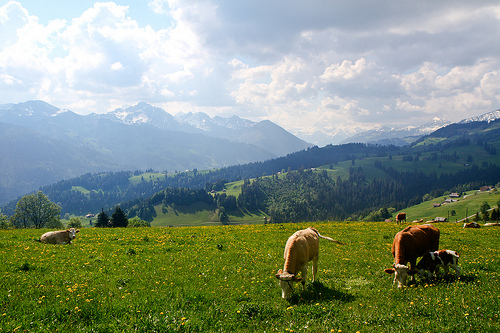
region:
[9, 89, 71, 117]
highest peak in distance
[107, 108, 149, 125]
white snow on mountain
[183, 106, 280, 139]
group of mountains far off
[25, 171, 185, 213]
green hill covered in trees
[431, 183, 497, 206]
group of buildings on hill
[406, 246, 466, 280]
small calf by red cow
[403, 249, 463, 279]
calf is red and white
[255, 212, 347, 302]
can is cream colored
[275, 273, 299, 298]
white face of eating cow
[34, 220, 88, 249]
cow laying in green meadow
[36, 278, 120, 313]
Yellow flowers in the class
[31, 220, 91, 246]
A cow looking guilty in the field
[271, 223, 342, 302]
A yellow cow eating grass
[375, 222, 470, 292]
A cow and her baby eating together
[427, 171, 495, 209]
Houses in a community on the mountain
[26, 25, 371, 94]
The sky is cloudy and blue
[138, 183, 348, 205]
Trees on a mountain with green leaves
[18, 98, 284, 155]
Very tall mountains clustered together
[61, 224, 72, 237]
The ear of a cow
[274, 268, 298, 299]
The head of a cow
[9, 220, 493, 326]
lush green grass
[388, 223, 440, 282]
the brown cow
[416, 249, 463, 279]
the small brown and white cow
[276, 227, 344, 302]
the light colored cow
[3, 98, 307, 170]
the mountains in the far distance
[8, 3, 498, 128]
the clouds in the sky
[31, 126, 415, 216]
the trees in the mountain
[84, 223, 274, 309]
the yellow flowers on the grass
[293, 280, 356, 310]
the shadow on the grass from the light colored cow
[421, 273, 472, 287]
the shadow on the grass near the small cow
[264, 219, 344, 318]
the cow is eating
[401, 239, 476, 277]
the cow is is brown and white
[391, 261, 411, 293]
the head is white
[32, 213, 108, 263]
the cow is on the ground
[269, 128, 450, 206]
the tree has hills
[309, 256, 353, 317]
the shadow is on the grass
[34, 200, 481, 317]
the cows are five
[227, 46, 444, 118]
the clouds are in the sky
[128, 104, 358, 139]
mountains are in the bakground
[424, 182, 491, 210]
housesa are on the hill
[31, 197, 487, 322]
a group of cows on the mountainside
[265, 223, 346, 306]
a yellow cow eating grass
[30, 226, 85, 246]
a cow sitting in the grass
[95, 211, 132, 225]
tree in meadow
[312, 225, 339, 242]
tail of cow swinging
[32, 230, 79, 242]
cow laying in grass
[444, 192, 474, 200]
building behind group of cows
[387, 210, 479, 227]
group of cows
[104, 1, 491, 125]
large dark clouds in sky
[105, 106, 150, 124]
snow on a mountain top